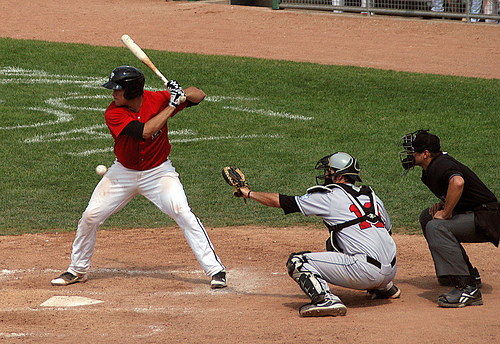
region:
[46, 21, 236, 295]
batter holding a bat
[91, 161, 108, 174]
small white baseball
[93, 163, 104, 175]
baseball flying through the air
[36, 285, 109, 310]
dirt on home plate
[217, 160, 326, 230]
arm is outstretched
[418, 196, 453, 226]
hands on the thighs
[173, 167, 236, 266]
black stripe on the side of the pant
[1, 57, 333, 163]
white paint in the grass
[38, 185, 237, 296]
legs are spread wide apart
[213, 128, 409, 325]
catcher crouching in the dirt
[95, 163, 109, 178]
A baseball flying through the air, about to be caught by the catcher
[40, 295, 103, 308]
Home plate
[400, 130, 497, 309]
The umpire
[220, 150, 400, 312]
The catcher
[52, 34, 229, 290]
The batter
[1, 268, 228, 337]
The batter's box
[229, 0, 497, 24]
The dugout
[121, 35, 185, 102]
A regulation size, wooden baseball bat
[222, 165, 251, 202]
A brown and black, leather catcher's mitt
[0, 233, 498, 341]
Red infield clay, the preferred medium in baseball for the infield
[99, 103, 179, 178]
the shirt is red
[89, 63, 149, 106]
the helmet is black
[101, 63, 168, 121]
the helmet is black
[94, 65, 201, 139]
the helmet is black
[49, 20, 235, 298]
The man is wearing a baseball uniform.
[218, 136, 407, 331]
The man is wearing a baseball uniform.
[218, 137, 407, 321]
The man is wearing a baseball glove.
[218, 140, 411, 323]
The man is wearing a face guard.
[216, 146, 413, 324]
The man is crouching.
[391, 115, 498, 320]
The man is crouching.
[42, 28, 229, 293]
The man is holding a baseball bat.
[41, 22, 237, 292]
The man is wearing a baseball helmet.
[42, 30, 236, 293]
The man is wearing gloves.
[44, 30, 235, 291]
The man's knees are slightly bent.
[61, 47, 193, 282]
this is a baseball player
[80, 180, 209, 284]
these are the legs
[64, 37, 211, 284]
he is swinging the bat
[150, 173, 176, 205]
the trouser is white in color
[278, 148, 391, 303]
the player is squatting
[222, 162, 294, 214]
the hand is in front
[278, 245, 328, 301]
this is the leg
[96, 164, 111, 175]
this is the ball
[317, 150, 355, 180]
this is an helmet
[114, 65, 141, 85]
the helmet is black in color